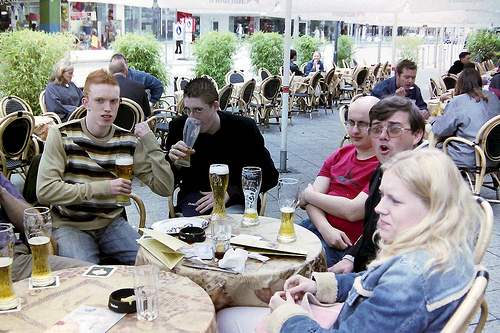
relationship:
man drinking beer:
[174, 71, 244, 170] [108, 117, 276, 245]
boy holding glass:
[49, 66, 136, 164] [108, 149, 136, 217]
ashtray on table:
[168, 207, 219, 254] [231, 225, 296, 258]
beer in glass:
[108, 117, 276, 245] [108, 149, 136, 217]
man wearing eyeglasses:
[174, 71, 244, 170] [179, 102, 214, 125]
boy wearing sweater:
[49, 66, 136, 164] [43, 126, 156, 262]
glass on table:
[108, 149, 136, 217] [231, 225, 296, 258]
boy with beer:
[49, 66, 136, 164] [108, 117, 276, 245]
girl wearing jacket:
[350, 157, 460, 293] [343, 255, 428, 331]